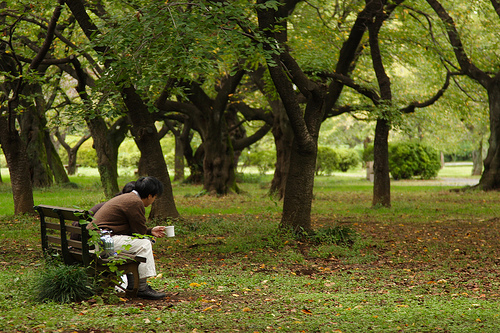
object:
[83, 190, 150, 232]
sweater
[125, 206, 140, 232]
brown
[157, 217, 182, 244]
cup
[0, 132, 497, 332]
floor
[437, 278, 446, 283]
leaf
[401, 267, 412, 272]
leaf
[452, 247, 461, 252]
leaf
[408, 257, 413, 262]
leaf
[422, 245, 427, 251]
leaf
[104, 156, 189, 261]
man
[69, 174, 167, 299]
couple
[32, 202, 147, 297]
bench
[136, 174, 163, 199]
hair